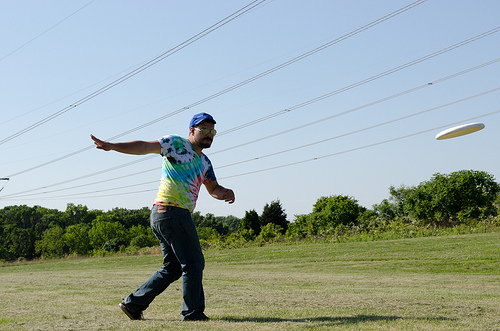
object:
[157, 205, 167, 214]
brand tag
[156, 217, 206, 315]
leg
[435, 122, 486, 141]
frisbee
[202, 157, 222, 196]
arms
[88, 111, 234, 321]
man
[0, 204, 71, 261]
tree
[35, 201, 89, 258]
tree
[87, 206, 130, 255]
tree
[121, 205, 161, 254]
tree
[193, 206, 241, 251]
tree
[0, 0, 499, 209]
sky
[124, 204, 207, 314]
jeans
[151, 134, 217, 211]
shirt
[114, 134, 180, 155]
arm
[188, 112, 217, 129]
blue hat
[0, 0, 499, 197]
power lines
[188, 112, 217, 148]
head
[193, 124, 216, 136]
glass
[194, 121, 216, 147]
face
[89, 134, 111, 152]
hand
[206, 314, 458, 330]
shadow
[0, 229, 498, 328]
grass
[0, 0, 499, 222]
air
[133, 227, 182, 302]
leg